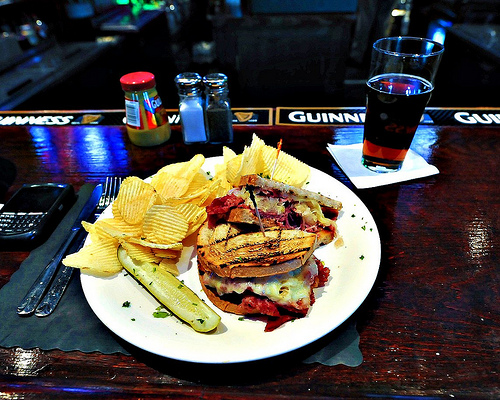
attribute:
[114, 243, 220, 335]
pickle — long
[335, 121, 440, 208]
napkin — white 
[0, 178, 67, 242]
cell phone — black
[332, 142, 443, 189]
napkin — white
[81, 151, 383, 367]
plate — round, white, green 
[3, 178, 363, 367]
placemat — partially visible, black, paper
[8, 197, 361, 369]
mat — green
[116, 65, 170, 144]
condiment — yellow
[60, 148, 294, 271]
potato chips — ruffles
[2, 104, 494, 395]
table — wooden, dark, highly-polished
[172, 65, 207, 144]
salt shaker — salt 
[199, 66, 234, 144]
pepper shaker — pepper 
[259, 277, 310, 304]
cheese — melted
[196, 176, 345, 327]
sandwich — pastrami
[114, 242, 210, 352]
pickle — slice 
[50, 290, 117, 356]
place mat — Greenish , gray 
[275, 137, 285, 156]
top — orange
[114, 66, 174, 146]
jar — closed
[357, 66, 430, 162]
liquid — dark